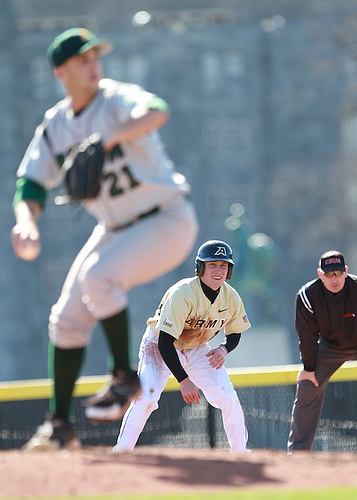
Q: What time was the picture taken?
A: Daytime.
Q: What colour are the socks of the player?
A: Green.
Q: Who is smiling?
A: The man in the middle.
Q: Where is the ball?
A: In the first man's hand.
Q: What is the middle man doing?
A: Bending.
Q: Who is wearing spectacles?
A: The man in black.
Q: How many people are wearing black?
A: One.